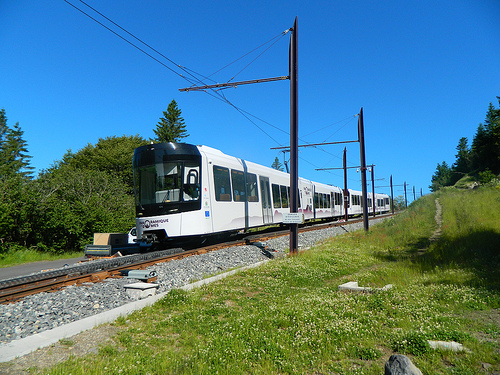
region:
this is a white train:
[127, 139, 394, 248]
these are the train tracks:
[2, 245, 179, 302]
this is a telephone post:
[288, 25, 298, 253]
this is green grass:
[91, 180, 498, 372]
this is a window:
[133, 140, 200, 215]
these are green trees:
[2, 94, 188, 255]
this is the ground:
[3, 303, 495, 373]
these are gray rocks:
[1, 278, 121, 343]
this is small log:
[378, 351, 424, 372]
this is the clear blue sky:
[0, 0, 498, 142]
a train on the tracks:
[89, 52, 321, 277]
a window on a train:
[106, 98, 274, 235]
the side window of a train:
[166, 143, 332, 222]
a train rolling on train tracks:
[102, 47, 344, 295]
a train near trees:
[97, 88, 269, 223]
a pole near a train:
[251, 24, 353, 306]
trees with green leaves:
[38, 161, 100, 261]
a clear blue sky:
[346, 25, 471, 111]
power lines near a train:
[166, 65, 391, 180]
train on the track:
[118, 133, 400, 251]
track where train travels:
[8, 260, 77, 283]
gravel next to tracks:
[22, 296, 71, 313]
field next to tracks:
[185, 283, 476, 368]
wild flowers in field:
[303, 310, 353, 332]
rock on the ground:
[383, 351, 428, 373]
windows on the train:
[217, 171, 257, 193]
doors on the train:
[259, 175, 273, 218]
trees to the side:
[44, 103, 186, 227]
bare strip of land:
[419, 200, 446, 269]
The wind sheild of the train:
[135, 169, 195, 201]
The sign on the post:
[278, 213, 303, 222]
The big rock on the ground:
[386, 349, 428, 369]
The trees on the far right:
[434, 99, 498, 184]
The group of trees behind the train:
[6, 104, 172, 247]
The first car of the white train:
[134, 147, 312, 233]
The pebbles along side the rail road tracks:
[0, 172, 395, 307]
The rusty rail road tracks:
[5, 143, 384, 275]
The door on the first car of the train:
[256, 178, 275, 225]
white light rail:
[144, 156, 294, 221]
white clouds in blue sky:
[24, 13, 71, 49]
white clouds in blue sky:
[421, 29, 438, 60]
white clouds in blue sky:
[421, 106, 442, 131]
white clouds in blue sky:
[76, 52, 112, 90]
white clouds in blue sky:
[27, 83, 80, 125]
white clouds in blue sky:
[140, 24, 194, 53]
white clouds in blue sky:
[309, 45, 395, 85]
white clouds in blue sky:
[209, 110, 256, 147]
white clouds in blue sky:
[70, 18, 117, 52]